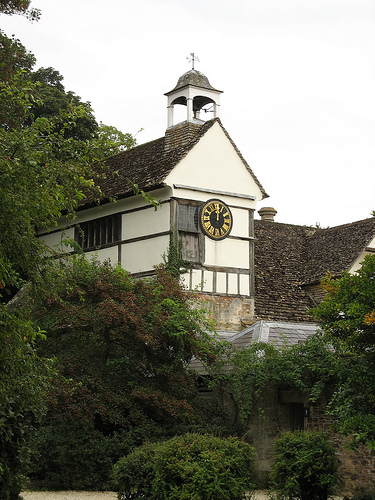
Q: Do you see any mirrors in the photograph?
A: No, there are no mirrors.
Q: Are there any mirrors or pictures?
A: No, there are no mirrors or pictures.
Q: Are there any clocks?
A: Yes, there is a clock.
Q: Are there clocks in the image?
A: Yes, there is a clock.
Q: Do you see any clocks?
A: Yes, there is a clock.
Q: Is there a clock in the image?
A: Yes, there is a clock.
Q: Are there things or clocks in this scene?
A: Yes, there is a clock.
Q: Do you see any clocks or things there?
A: Yes, there is a clock.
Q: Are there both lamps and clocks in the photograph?
A: No, there is a clock but no lamps.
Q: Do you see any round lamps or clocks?
A: Yes, there is a round clock.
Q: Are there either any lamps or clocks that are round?
A: Yes, the clock is round.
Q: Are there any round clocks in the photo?
A: Yes, there is a round clock.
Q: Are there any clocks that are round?
A: Yes, there is a clock that is round.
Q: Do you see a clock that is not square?
A: Yes, there is a round clock.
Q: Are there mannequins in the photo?
A: No, there are no mannequins.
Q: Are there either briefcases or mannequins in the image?
A: No, there are no mannequins or briefcases.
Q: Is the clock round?
A: Yes, the clock is round.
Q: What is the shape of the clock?
A: The clock is round.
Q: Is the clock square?
A: No, the clock is round.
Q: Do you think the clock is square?
A: No, the clock is round.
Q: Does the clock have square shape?
A: No, the clock is round.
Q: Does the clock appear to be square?
A: No, the clock is round.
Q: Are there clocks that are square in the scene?
A: No, there is a clock but it is round.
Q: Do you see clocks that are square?
A: No, there is a clock but it is round.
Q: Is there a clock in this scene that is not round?
A: No, there is a clock but it is round.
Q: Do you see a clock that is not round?
A: No, there is a clock but it is round.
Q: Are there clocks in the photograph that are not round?
A: No, there is a clock but it is round.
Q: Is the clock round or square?
A: The clock is round.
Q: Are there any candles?
A: No, there are no candles.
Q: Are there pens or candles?
A: No, there are no candles or pens.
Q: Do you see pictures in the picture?
A: No, there are no pictures.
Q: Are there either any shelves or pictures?
A: No, there are no pictures or shelves.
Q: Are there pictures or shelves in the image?
A: No, there are no pictures or shelves.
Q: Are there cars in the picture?
A: No, there are no cars.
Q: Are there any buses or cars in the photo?
A: No, there are no cars or buses.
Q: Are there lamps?
A: No, there are no lamps.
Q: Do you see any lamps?
A: No, there are no lamps.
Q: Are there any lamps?
A: No, there are no lamps.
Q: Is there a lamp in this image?
A: No, there are no lamps.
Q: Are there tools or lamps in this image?
A: No, there are no lamps or tools.